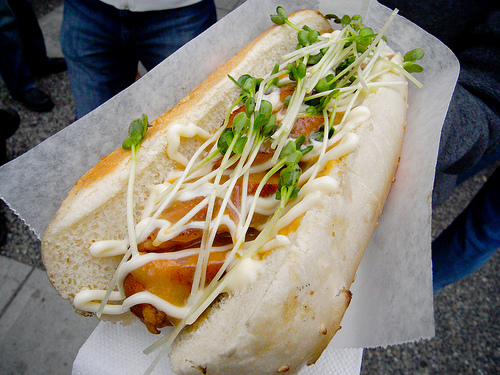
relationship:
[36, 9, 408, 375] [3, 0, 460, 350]
hot dog on a paper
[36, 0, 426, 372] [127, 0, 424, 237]
hot dog on bun covered in cheese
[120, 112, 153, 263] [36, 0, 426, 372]
garnish on hot dog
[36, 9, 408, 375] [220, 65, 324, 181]
hot dog with toppings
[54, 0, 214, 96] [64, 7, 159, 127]
man wearing jeans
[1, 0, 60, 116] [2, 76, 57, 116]
man wearing shoe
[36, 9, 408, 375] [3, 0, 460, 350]
hot dog on paper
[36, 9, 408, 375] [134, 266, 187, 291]
hot dog has cheese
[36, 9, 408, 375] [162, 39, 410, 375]
hot dog covered in bun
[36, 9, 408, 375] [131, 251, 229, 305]
hot dog with a cheese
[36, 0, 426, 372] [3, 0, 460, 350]
hot dog on paper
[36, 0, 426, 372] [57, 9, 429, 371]
hot dog on bun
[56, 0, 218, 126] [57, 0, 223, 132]
man wears jeans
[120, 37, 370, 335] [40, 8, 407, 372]
dog on bun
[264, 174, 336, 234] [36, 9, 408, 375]
topping on hot dog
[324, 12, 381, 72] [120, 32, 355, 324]
sprouts on hot dog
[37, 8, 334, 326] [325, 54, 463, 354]
bun on holder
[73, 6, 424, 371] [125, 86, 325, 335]
garnish on hot dog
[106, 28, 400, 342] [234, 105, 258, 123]
wiener has ketchup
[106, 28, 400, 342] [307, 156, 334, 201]
wiener has mustard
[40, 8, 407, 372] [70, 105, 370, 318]
bun has mayonaise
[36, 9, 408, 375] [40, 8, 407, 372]
hot dog has bun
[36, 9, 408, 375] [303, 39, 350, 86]
hot dog has toppings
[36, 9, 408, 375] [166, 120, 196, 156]
hot dog has mayo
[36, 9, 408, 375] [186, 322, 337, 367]
hot dog has bun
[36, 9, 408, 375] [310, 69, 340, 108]
hot dog has onion